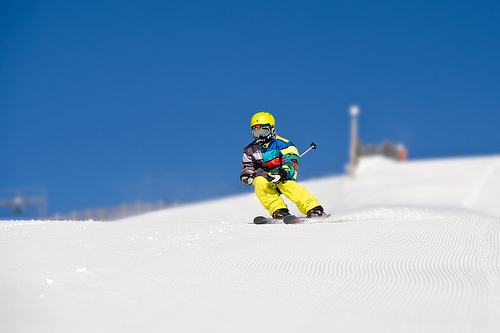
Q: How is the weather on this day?
A: It is clear.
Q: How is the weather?
A: It is clear.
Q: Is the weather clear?
A: Yes, it is clear.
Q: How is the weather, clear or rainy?
A: It is clear.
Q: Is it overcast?
A: No, it is clear.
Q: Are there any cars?
A: No, there are no cars.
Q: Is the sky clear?
A: Yes, the sky is clear.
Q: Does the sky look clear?
A: Yes, the sky is clear.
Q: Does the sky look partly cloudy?
A: No, the sky is clear.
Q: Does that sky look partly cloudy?
A: No, the sky is clear.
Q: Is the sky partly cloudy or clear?
A: The sky is clear.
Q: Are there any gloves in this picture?
A: Yes, there are gloves.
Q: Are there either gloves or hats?
A: Yes, there are gloves.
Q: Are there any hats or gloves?
A: Yes, there are gloves.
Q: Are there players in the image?
A: No, there are no players.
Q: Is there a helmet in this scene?
A: Yes, there is a helmet.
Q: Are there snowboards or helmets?
A: Yes, there is a helmet.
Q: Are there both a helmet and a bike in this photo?
A: No, there is a helmet but no bikes.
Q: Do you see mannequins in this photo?
A: No, there are no mannequins.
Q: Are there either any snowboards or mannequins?
A: No, there are no mannequins or snowboards.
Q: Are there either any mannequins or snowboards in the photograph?
A: No, there are no mannequins or snowboards.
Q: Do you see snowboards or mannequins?
A: No, there are no mannequins or snowboards.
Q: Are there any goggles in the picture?
A: Yes, there are goggles.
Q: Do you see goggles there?
A: Yes, there are goggles.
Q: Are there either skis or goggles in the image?
A: Yes, there are goggles.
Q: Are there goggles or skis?
A: Yes, there are goggles.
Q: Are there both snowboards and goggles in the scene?
A: No, there are goggles but no snowboards.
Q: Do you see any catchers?
A: No, there are no catchers.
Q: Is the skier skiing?
A: Yes, the skier is skiing.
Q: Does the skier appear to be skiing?
A: Yes, the skier is skiing.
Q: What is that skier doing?
A: The skier is skiing.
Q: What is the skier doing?
A: The skier is skiing.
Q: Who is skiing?
A: The skier is skiing.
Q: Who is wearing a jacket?
A: The skier is wearing a jacket.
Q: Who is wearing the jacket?
A: The skier is wearing a jacket.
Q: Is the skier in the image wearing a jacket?
A: Yes, the skier is wearing a jacket.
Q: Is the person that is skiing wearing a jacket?
A: Yes, the skier is wearing a jacket.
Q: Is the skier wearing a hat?
A: No, the skier is wearing a jacket.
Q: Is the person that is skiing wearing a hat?
A: No, the skier is wearing a jacket.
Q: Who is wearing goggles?
A: The skier is wearing goggles.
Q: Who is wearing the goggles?
A: The skier is wearing goggles.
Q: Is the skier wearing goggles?
A: Yes, the skier is wearing goggles.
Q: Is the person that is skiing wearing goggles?
A: Yes, the skier is wearing goggles.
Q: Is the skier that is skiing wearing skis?
A: No, the skier is wearing goggles.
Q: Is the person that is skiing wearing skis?
A: No, the skier is wearing goggles.